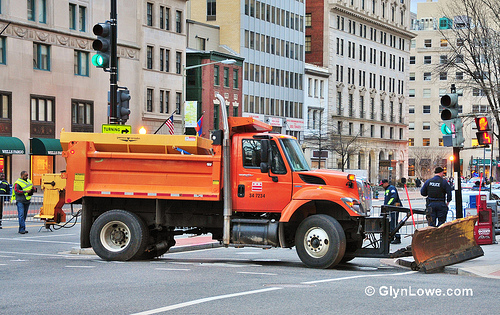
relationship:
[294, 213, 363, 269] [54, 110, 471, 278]
wheel on orange truck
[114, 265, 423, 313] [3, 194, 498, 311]
lines on road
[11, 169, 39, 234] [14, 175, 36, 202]
construction worker has vest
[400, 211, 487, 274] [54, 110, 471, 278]
snow plow on orange truck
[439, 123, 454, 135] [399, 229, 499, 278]
light on sidewalk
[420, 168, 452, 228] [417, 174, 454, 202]
man has shirt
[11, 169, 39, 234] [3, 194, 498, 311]
construction worker standing on road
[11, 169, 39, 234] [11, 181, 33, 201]
construction worker wearing vest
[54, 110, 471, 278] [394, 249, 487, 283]
orange truck crashed into curb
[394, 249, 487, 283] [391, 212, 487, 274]
curb with snow plow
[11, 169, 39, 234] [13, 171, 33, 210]
construction worker wearing a vest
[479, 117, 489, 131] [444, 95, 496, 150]
hand on traffic light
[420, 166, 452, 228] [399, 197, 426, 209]
man beside road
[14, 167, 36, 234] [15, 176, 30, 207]
construction worker wearing a vest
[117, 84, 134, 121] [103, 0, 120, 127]
traffic light on pole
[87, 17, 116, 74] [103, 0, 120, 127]
traffic light on pole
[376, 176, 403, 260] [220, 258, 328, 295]
police officer on street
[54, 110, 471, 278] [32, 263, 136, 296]
orange truck on street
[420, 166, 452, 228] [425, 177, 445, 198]
man wearing shirt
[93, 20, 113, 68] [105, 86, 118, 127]
traffic light on a light post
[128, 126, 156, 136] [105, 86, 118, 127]
sign on a light post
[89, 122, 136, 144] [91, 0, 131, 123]
sign on light post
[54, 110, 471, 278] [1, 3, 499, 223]
orange truck in city